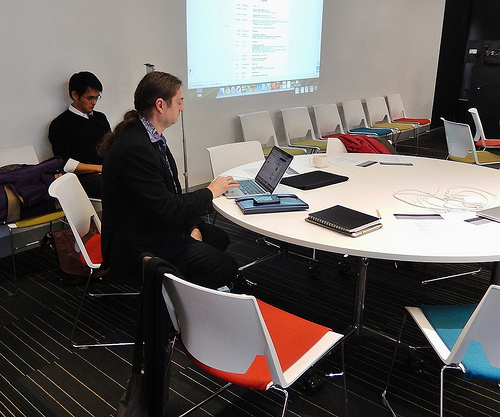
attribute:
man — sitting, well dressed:
[101, 72, 238, 347]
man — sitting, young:
[48, 68, 107, 195]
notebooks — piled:
[304, 204, 382, 239]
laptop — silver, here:
[222, 145, 295, 199]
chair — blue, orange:
[140, 254, 353, 416]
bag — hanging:
[121, 248, 172, 415]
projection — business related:
[186, 0, 323, 106]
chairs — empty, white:
[2, 93, 431, 276]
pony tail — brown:
[95, 111, 157, 174]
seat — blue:
[419, 301, 498, 374]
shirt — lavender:
[139, 113, 182, 194]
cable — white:
[396, 182, 499, 215]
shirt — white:
[66, 102, 95, 120]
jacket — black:
[103, 121, 215, 277]